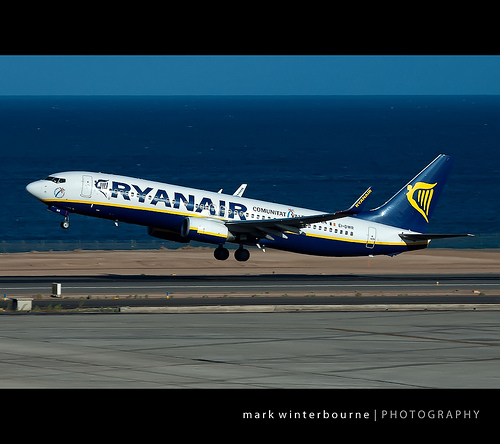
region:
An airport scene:
[6, 75, 492, 371]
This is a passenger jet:
[21, 129, 479, 285]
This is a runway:
[4, 274, 496, 385]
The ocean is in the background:
[156, 94, 374, 175]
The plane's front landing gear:
[44, 201, 86, 234]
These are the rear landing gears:
[206, 240, 256, 269]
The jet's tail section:
[374, 148, 479, 262]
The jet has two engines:
[146, 210, 236, 247]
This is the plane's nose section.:
[20, 166, 76, 208]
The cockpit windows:
[40, 168, 72, 185]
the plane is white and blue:
[29, 108, 439, 336]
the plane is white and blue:
[29, 85, 332, 272]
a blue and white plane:
[25, 131, 470, 288]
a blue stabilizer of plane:
[364, 143, 456, 233]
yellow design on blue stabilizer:
[399, 174, 444, 230]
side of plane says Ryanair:
[93, 170, 260, 232]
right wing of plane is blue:
[227, 201, 373, 247]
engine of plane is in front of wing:
[180, 211, 234, 250]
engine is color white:
[168, 214, 239, 244]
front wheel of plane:
[54, 210, 76, 234]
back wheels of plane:
[204, 239, 256, 269]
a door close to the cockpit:
[19, 168, 96, 213]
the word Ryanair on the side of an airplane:
[103, 176, 260, 235]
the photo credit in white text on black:
[226, 396, 485, 431]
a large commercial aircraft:
[14, 136, 464, 287]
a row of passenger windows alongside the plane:
[101, 183, 368, 253]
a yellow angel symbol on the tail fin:
[400, 172, 444, 244]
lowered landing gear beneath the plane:
[53, 208, 288, 275]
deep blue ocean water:
[216, 121, 365, 166]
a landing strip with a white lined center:
[103, 276, 413, 298]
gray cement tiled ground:
[103, 313, 483, 385]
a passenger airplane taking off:
[12, 116, 496, 397]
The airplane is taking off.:
[43, 146, 468, 283]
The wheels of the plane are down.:
[208, 238, 253, 267]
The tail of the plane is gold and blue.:
[385, 153, 457, 228]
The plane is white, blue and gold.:
[41, 152, 458, 281]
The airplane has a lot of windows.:
[254, 210, 362, 238]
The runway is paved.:
[108, 300, 408, 387]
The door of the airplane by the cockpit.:
[74, 171, 106, 202]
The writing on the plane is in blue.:
[105, 171, 255, 246]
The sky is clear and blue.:
[104, 62, 449, 104]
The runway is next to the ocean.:
[21, 99, 498, 271]